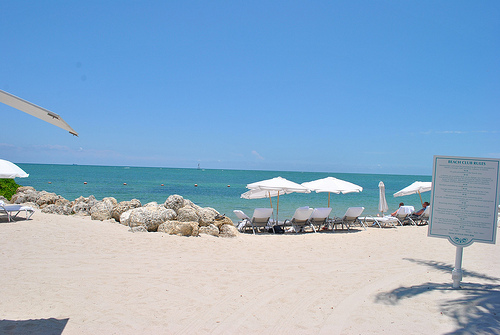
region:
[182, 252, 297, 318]
brown sand on the beach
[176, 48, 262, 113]
blue sky above land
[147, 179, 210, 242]
rocks on the land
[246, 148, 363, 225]
white umbrellas on beach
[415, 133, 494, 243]
sign on the beach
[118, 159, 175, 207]
blue water next to the beach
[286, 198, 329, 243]
chairs under the umbrellas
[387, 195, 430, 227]
people in the chairs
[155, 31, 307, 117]
blue sky with no clouds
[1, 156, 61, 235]
recliner under an umbrella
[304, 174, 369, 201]
Extended umbrella shading a lounge chair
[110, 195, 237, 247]
Large boulders on the beach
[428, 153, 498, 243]
Sign anchored in sand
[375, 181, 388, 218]
Unextended shade umbrella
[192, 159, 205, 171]
Ship or oil platform very far in the distance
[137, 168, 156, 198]
Large body of water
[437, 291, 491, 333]
Shadow cast in sand by palm tree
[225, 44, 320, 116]
Very clear blue sky of a summer day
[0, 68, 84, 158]
Opened side panel of a vendors truck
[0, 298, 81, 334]
Shadow casting sand by side panel of vendors truck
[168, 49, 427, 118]
this is the sky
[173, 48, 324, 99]
the sky is blue in color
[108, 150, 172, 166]
the sky has some clouds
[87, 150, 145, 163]
the clouds are white in color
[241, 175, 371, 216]
these are some umbrellas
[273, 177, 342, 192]
the umbrellas are white in color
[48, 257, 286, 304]
this is the ground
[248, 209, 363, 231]
these are some seats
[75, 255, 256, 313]
the ground is full of sand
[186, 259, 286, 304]
the sand is brown in color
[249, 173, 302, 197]
a large white beach umbrella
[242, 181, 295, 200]
a large white beach umbrella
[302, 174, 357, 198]
a large white beach umbrella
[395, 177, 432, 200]
a large white beach umbrella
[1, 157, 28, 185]
a large white beach umbrella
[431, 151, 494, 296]
a large white sign on the beach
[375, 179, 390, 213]
a large white beach umbrella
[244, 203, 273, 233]
a white beach chair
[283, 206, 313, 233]
a white beach chair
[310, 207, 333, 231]
a white beach chair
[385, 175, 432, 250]
Peope sitting on beach under open umbrella.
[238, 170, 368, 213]
Three white open umbrellas on beach.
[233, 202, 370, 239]
Five lounge chairs sitting on beach.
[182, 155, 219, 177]
Sail boat far out on water.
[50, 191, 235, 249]
Huge rocks piled along portion of beach.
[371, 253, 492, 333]
Shadow of palm tree fronds on sand.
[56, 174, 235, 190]
String of floats out in water.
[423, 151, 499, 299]
White sign trimmed in blue standing on beach.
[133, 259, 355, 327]
White sand on beach.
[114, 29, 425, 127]
Clear blue sky over water.